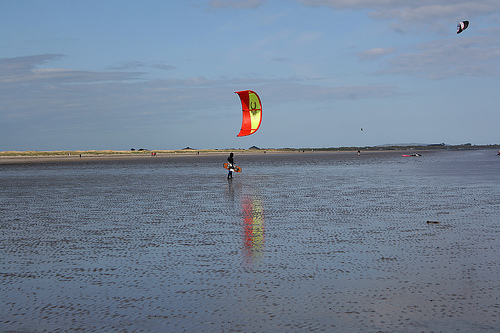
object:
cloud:
[351, 45, 403, 60]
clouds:
[0, 52, 67, 73]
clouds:
[194, 0, 267, 14]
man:
[226, 152, 234, 180]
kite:
[402, 152, 422, 157]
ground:
[0, 149, 440, 162]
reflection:
[241, 196, 265, 265]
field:
[0, 142, 500, 165]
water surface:
[0, 152, 497, 333]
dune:
[181, 147, 196, 151]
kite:
[235, 90, 263, 138]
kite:
[456, 20, 469, 34]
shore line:
[6, 152, 500, 156]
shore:
[0, 147, 500, 333]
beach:
[0, 147, 500, 333]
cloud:
[352, 0, 500, 35]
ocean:
[0, 152, 498, 332]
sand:
[206, 171, 257, 187]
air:
[0, 0, 499, 153]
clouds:
[90, 116, 130, 135]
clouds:
[150, 63, 179, 72]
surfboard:
[223, 162, 243, 173]